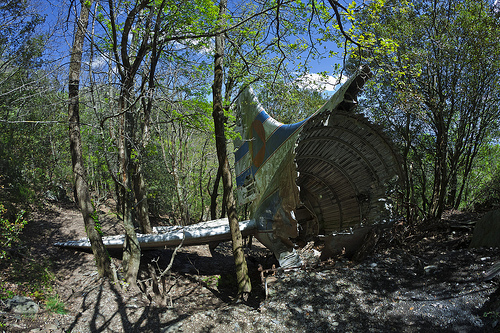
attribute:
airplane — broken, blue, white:
[37, 65, 446, 270]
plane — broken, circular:
[215, 75, 395, 245]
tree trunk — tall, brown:
[199, 59, 251, 290]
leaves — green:
[349, 8, 409, 29]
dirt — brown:
[264, 266, 310, 294]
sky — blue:
[312, 45, 328, 68]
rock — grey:
[8, 290, 42, 320]